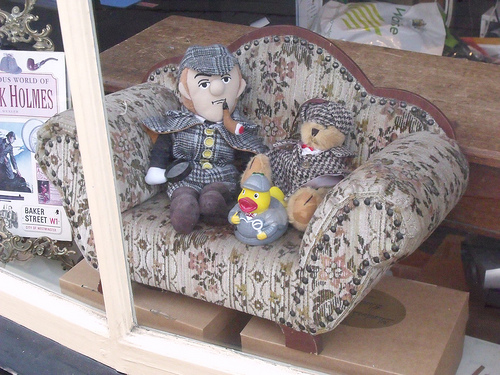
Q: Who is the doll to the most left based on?
A: Sherlock Holmes.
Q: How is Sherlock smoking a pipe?
A: Without using his hands.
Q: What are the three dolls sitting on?
A: A miniature couch.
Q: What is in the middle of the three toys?
A: A duck.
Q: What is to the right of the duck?
A: A stuffed bear.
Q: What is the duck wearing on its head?
A: A hat.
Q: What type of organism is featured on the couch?
A: The flower.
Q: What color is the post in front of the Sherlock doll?
A: White.